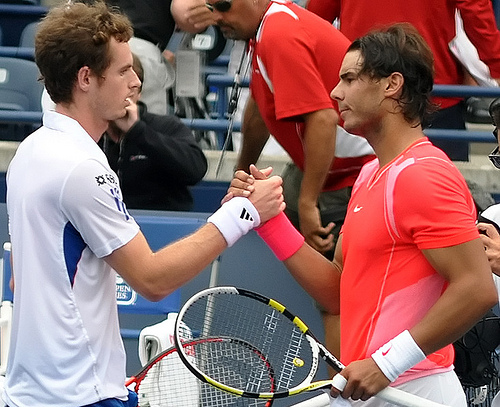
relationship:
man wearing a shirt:
[219, 22, 499, 406] [337, 136, 481, 387]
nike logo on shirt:
[353, 204, 363, 212] [337, 136, 481, 387]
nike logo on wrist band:
[381, 343, 391, 356] [371, 328, 426, 383]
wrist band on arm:
[207, 196, 260, 248] [60, 158, 286, 300]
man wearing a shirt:
[4, 0, 286, 406] [4, 109, 141, 406]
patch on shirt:
[64, 221, 88, 291] [4, 109, 141, 406]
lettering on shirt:
[94, 174, 118, 187] [4, 109, 141, 406]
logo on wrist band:
[239, 207, 255, 222] [207, 196, 260, 248]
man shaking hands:
[4, 0, 291, 406] [219, 163, 285, 229]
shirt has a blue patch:
[4, 109, 141, 406] [64, 221, 88, 291]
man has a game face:
[219, 22, 499, 406] [330, 48, 387, 135]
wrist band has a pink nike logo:
[371, 328, 426, 383] [381, 343, 391, 356]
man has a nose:
[219, 22, 499, 406] [330, 80, 347, 100]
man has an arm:
[219, 22, 499, 406] [328, 164, 499, 401]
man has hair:
[4, 0, 286, 406] [34, 0, 133, 109]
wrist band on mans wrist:
[207, 196, 260, 248] [205, 195, 260, 248]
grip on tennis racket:
[372, 384, 450, 406] [174, 285, 451, 406]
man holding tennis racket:
[219, 22, 499, 406] [174, 285, 451, 406]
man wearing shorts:
[4, 0, 286, 406] [81, 388, 137, 405]